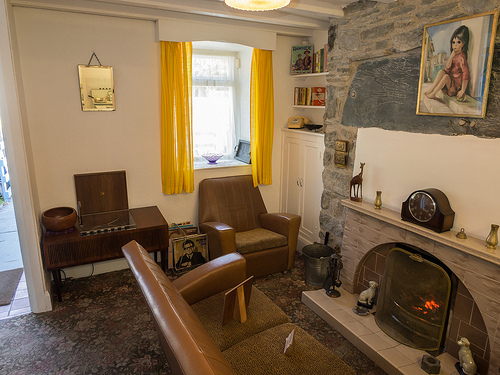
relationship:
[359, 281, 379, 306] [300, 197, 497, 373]
animal figurine by fireplace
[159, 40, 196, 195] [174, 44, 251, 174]
curtains on window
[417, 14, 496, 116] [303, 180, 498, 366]
painting above fireplace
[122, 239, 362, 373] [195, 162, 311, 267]
couch by armchair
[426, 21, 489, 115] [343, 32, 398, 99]
painting on wall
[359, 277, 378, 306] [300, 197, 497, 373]
animal figurine on fireplace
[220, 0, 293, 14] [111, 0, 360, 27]
fixture on ceiling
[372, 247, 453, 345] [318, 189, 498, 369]
fireplace guard on fireplace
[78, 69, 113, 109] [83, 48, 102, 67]
plaque on string